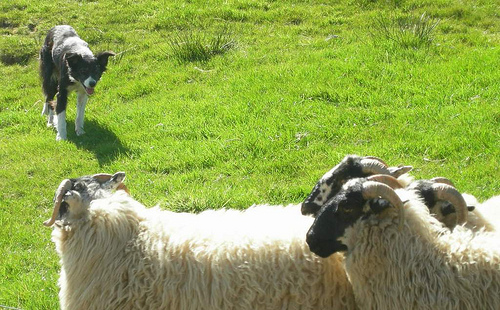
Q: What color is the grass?
A: Green.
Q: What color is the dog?
A: Black and white.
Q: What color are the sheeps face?
A: Black.